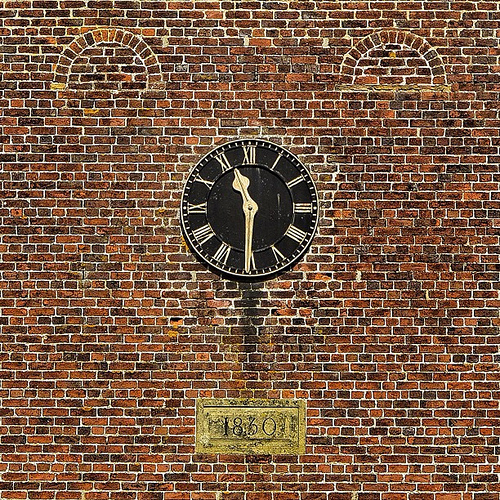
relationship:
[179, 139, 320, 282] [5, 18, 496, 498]
clock on wall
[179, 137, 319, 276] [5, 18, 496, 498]
black clock on wall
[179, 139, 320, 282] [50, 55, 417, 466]
clock on wall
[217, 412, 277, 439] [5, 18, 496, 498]
inscription on wall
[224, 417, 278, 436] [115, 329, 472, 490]
1860 on wall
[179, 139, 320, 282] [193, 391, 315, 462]
clock constructed 1860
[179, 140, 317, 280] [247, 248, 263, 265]
clock covering numeral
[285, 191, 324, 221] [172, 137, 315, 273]
number on clock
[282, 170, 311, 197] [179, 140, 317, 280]
number on a clock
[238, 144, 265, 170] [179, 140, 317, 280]
number on a clock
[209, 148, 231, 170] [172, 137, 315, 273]
number on a clock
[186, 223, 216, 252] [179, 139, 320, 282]
number on a clock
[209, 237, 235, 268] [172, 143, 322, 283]
number on a clock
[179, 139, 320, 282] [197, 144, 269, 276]
clock reads 11:30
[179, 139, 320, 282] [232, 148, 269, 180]
clock has marks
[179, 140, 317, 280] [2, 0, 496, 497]
clock on building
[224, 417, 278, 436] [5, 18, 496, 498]
1860 on wall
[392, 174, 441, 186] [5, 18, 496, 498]
bricks on wall